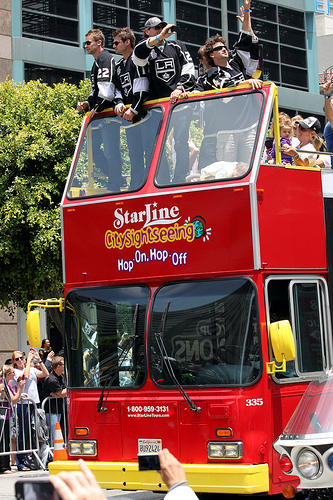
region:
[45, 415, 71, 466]
the cone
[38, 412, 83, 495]
the cone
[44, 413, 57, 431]
the cone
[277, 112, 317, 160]
woman carrying a baby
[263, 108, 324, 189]
woman carrying a baby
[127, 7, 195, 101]
a football player on a bus.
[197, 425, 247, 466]
a left front headlight.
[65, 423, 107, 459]
a right front headlight.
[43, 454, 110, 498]
a hand above a crowd.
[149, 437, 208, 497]
a hand in front of a truck.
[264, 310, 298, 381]
a yellow side view mirror.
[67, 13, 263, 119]
a group of people on a bus.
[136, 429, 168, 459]
a license plate on a truck.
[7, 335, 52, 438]
a man standing behind a baracade.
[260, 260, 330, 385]
a side door window.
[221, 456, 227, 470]
part of a light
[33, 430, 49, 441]
part of a rail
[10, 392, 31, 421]
part of a shirt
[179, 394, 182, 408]
part of a wiper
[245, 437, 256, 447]
edge of a bus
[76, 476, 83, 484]
part of a finger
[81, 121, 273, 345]
this is a bus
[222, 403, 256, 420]
the bus is red in color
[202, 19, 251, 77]
this is a man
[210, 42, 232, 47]
this is a spectacle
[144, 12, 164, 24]
this is a cap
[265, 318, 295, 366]
this is a side mirror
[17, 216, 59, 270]
this is a tree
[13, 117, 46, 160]
the leaves are green in color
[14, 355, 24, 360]
dark black sunglasses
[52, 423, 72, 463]
a tall orange and white cone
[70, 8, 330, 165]
People on top of a double decker bus.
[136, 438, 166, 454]
A license plate on the front of a bus.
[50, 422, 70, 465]
An orange and white traffic cone.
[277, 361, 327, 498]
A white motorcycle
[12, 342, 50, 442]
A person wearing sunglasses.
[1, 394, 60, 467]
A grey fence.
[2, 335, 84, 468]
people standing on the sidewalk.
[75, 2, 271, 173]
people standing up on a bus.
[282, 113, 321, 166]
A person holding a child.